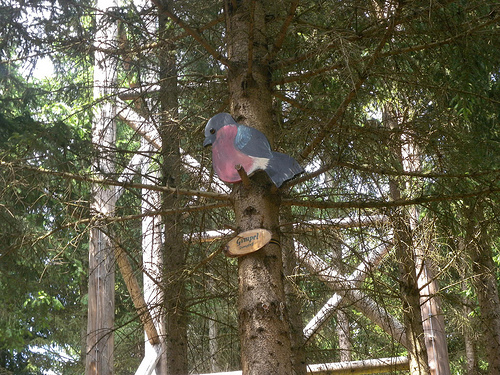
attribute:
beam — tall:
[84, 4, 123, 373]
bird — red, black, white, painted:
[195, 111, 305, 192]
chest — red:
[209, 137, 250, 182]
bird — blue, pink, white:
[199, 109, 312, 188]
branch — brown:
[231, 160, 255, 195]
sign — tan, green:
[221, 228, 278, 257]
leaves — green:
[0, 239, 69, 320]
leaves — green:
[17, 282, 67, 327]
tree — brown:
[1, 182, 142, 372]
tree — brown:
[103, 6, 398, 373]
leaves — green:
[155, 13, 213, 75]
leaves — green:
[421, 38, 484, 83]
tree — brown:
[283, 7, 481, 373]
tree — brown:
[268, 6, 468, 373]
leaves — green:
[370, 269, 410, 309]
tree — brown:
[218, 0, 310, 371]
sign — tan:
[222, 227, 276, 256]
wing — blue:
[229, 123, 272, 157]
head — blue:
[200, 110, 240, 150]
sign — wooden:
[225, 226, 275, 251]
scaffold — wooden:
[97, 107, 377, 349]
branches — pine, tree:
[31, 134, 160, 188]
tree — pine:
[191, 68, 302, 349]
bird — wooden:
[197, 104, 303, 195]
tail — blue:
[266, 150, 300, 188]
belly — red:
[210, 137, 260, 177]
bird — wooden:
[200, 109, 287, 189]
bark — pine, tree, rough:
[252, 284, 282, 341]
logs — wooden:
[296, 243, 366, 289]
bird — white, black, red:
[194, 104, 301, 187]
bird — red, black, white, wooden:
[197, 108, 299, 186]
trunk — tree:
[214, 127, 292, 263]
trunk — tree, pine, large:
[225, 167, 279, 333]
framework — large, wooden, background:
[89, 60, 449, 337]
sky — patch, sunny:
[15, 10, 59, 87]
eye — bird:
[203, 123, 218, 136]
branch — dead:
[78, 199, 200, 220]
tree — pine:
[205, 79, 311, 333]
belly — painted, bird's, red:
[208, 139, 256, 183]